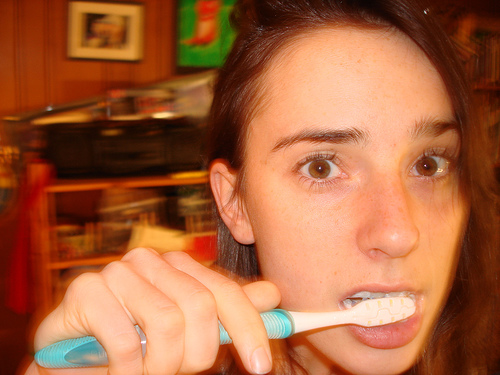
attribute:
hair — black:
[206, 1, 500, 374]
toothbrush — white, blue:
[32, 296, 418, 370]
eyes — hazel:
[299, 154, 452, 180]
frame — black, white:
[65, 0, 142, 61]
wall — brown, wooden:
[2, 2, 173, 187]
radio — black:
[46, 117, 206, 176]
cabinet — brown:
[26, 165, 217, 355]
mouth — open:
[340, 282, 426, 350]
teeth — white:
[345, 291, 420, 313]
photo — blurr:
[1, 1, 499, 374]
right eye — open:
[296, 156, 344, 182]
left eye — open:
[410, 154, 451, 180]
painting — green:
[177, 0, 237, 67]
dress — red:
[0, 171, 42, 315]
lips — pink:
[336, 282, 425, 349]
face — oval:
[242, 26, 472, 373]